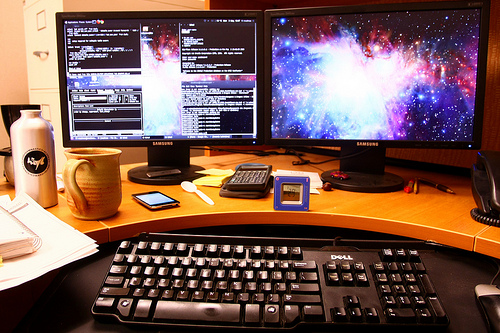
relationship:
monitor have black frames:
[61, 13, 253, 146] [55, 9, 265, 148]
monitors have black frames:
[263, 0, 491, 195] [265, 1, 487, 148]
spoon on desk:
[180, 175, 215, 202] [1, 147, 493, 277]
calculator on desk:
[225, 162, 273, 189] [61, 140, 499, 262]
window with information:
[177, 17, 257, 79] [66, 17, 255, 149]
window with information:
[178, 75, 254, 130] [66, 17, 255, 149]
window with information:
[64, 17, 142, 71] [66, 17, 255, 149]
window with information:
[62, 85, 142, 131] [66, 17, 255, 149]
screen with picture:
[260, 19, 480, 142] [276, 18, 479, 137]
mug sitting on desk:
[55, 119, 134, 231] [1, 123, 499, 283]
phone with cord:
[463, 148, 498, 228] [460, 197, 496, 236]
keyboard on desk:
[95, 236, 443, 331] [4, 136, 499, 331]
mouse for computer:
[469, 277, 497, 330] [50, 8, 262, 148]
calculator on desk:
[225, 162, 273, 189] [4, 149, 481, 229]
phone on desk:
[463, 148, 498, 228] [2, 147, 499, 257]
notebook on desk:
[0, 203, 42, 259] [2, 147, 499, 257]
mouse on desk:
[469, 277, 500, 332] [1, 246, 498, 330]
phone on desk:
[124, 182, 176, 217] [75, 137, 495, 247]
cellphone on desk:
[256, 169, 328, 219] [4, 156, 499, 289]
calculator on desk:
[228, 160, 274, 190] [2, 147, 499, 257]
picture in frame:
[37, 10, 46, 25] [33, 8, 47, 30]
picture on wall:
[37, 10, 46, 25] [24, 4, 53, 48]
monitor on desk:
[10, 13, 255, 177] [60, 160, 483, 241]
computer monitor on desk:
[264, 2, 492, 148] [2, 147, 499, 257]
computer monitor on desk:
[55, 8, 264, 149] [2, 147, 499, 257]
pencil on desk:
[412, 182, 423, 195] [359, 191, 446, 229]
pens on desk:
[400, 176, 459, 203] [359, 191, 446, 229]